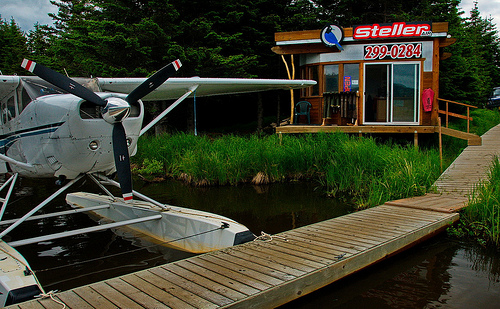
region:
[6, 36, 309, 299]
An airplane that can land on the water.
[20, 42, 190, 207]
The propeller on the front of the airplane.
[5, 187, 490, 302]
A body of water.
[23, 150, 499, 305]
A small dock leading up to the shore.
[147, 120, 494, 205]
Tall green grass on the shoreline.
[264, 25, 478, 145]
A small brown building.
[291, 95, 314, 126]
A green patio chair.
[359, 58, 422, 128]
Sliding glass doors on front of the building.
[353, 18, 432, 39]
The word steller on front of the building.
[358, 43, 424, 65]
The numbers 299-0284 on front of the building.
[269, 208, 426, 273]
wooden walkway above the water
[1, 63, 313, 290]
seaplane parked by a dock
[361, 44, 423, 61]
phone number above a sliding glass door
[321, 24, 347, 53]
logo with a bluebird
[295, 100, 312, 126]
plastic green chair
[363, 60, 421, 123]
open sliding glass door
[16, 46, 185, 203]
seaplane propeller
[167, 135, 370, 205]
green grasses growing along the water's edge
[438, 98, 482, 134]
wooden railing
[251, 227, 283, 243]
rope on the dock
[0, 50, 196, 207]
three black airplane propellers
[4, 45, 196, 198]
black propellers on an airplane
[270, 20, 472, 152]
brown wooden building in the grass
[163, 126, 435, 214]
tall lush grass growing by the water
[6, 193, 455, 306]
narrow wooden bridge over the water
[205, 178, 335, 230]
dark murky water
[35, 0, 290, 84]
green leaves on trees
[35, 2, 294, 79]
dense tree with leaves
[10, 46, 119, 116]
black propeller with white and red stripes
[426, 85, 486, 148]
wooden fence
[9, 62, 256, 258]
white helicopter on water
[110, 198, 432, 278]
wooden boardwalk to lake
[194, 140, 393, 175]
tall blades of grass near water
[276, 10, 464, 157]
small wooden storefront on hill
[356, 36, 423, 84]
red, black, and white numbers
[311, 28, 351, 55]
blue and black bird in logo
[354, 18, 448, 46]
steller white and red logo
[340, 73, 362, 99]
red and blue open sign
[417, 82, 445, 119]
red life jacket on side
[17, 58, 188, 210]
black blades on front of plane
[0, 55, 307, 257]
a white airplane in the water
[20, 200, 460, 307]
a wooden dock along the water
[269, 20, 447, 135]
a wood building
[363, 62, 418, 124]
a sliding glass door in the building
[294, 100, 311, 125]
a green chair outside the building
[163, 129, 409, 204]
long tall grass along the water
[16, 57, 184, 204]
a propeller on the front of the plane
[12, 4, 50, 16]
clouds in the sky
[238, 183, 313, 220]
the water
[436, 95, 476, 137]
a wooden hand rail